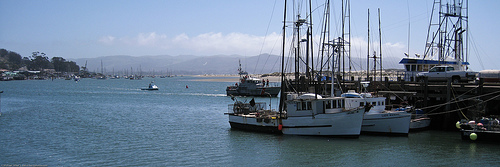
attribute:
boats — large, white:
[257, 90, 411, 160]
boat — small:
[138, 84, 176, 108]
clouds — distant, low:
[146, 33, 209, 66]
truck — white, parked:
[413, 60, 466, 88]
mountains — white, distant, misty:
[128, 54, 233, 84]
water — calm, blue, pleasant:
[83, 119, 145, 148]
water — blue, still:
[21, 80, 433, 157]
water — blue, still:
[68, 100, 122, 130]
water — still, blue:
[129, 117, 174, 150]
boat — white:
[275, 23, 355, 138]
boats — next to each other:
[274, 88, 415, 138]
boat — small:
[143, 77, 160, 97]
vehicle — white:
[415, 60, 474, 83]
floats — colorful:
[464, 115, 481, 126]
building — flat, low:
[399, 55, 457, 77]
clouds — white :
[129, 26, 257, 54]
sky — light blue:
[39, 2, 262, 51]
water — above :
[48, 101, 157, 160]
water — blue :
[54, 105, 173, 152]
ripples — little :
[112, 115, 142, 140]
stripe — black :
[285, 120, 335, 136]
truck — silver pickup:
[411, 57, 478, 83]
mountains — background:
[134, 27, 254, 80]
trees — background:
[1, 45, 83, 67]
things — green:
[455, 119, 476, 140]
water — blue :
[2, 70, 497, 163]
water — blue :
[0, 78, 496, 164]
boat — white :
[228, 90, 368, 140]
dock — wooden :
[283, 73, 495, 127]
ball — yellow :
[467, 132, 478, 139]